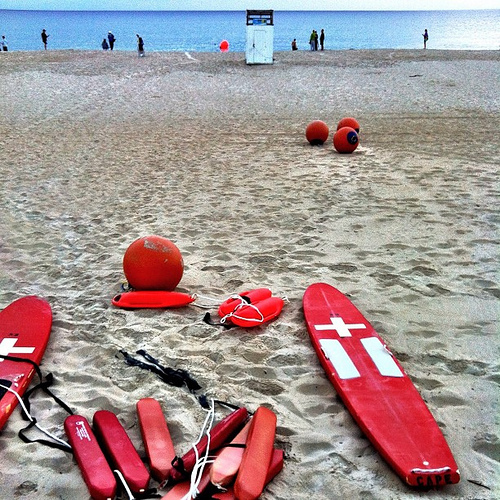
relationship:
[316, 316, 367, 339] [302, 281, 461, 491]
lifeguard cross on surfbard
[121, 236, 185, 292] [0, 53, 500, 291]
orange buoy's in sand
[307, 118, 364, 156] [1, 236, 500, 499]
red buoy's for lifeguards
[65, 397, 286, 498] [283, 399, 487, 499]
floaties are in a pile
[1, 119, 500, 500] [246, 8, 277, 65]
buoy's for lifeguard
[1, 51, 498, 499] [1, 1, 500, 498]
sand on beach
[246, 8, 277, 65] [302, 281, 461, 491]
lifeguard has a surfboard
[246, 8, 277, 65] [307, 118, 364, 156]
lifeguard has red buoy's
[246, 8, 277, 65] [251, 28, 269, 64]
lifeguard station has a door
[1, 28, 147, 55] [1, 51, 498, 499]
beach goers in sand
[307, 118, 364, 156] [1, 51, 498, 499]
three red buoy's in sand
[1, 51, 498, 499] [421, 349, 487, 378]
sand has foot prints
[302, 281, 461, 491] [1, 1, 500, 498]
rescue board on beach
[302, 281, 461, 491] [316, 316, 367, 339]
surboard has a rescue cross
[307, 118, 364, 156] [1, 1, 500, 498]
red buoy's on beach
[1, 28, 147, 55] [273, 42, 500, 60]
beach goers at shoreline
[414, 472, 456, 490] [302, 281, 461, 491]
writting on surfboard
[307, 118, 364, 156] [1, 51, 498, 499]
red buoy's on sand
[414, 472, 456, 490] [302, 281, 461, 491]
writting on rescue board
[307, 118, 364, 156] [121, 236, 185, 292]
floating red buoy's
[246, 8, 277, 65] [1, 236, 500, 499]
lifeguards have rescue equipment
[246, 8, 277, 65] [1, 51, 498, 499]
lifeguard stand in sand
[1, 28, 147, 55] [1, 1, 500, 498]
people on beach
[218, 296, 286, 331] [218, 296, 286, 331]
floating buoy's connected to floating buoy's